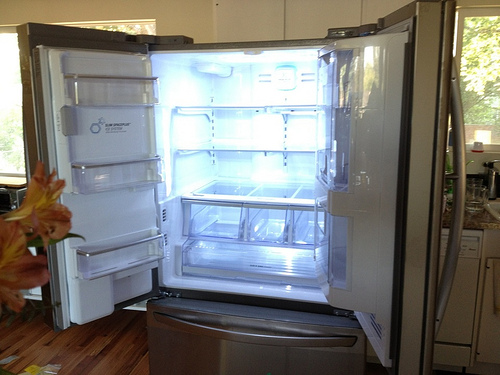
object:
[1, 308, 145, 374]
floor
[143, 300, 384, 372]
freezer refrigerator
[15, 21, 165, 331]
door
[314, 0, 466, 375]
door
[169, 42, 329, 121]
shefl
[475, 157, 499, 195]
cannister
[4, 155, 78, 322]
orange flowers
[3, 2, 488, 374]
picture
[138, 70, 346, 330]
shelves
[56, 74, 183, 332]
drawers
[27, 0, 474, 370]
freezer refrigirator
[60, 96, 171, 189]
ice maker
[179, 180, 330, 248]
boxes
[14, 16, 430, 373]
doors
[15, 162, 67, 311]
flower petals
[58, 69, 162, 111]
door shelf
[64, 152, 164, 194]
door shelf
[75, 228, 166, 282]
door shelf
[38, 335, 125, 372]
floors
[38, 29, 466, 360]
fridge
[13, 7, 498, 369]
kitchen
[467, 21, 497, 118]
trees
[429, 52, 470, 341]
handle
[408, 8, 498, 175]
window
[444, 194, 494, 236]
countertop